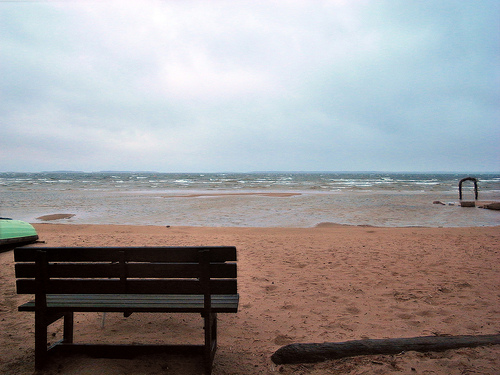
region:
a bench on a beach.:
[16, 239, 248, 356]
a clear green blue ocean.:
[0, 168, 498, 189]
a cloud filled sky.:
[0, 0, 499, 176]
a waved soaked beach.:
[0, 188, 497, 222]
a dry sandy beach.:
[7, 225, 495, 373]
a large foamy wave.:
[324, 173, 446, 190]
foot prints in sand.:
[377, 261, 452, 313]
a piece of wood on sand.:
[267, 315, 498, 364]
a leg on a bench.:
[194, 305, 235, 358]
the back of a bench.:
[9, 241, 257, 304]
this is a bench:
[2, 211, 272, 373]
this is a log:
[268, 293, 493, 373]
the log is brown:
[259, 310, 491, 373]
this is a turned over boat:
[0, 181, 42, 293]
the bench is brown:
[2, 222, 271, 369]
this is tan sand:
[273, 221, 449, 308]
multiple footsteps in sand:
[291, 230, 466, 330]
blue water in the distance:
[0, 141, 470, 193]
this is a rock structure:
[436, 157, 491, 217]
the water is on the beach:
[88, 176, 445, 267]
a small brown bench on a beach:
[11, 243, 243, 373]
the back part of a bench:
[8, 251, 248, 301]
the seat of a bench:
[18, 283, 249, 311]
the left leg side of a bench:
[22, 312, 84, 364]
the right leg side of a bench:
[175, 312, 236, 362]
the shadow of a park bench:
[97, 328, 149, 370]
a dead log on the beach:
[272, 315, 432, 373]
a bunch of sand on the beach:
[297, 252, 374, 307]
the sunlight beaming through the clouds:
[194, 35, 308, 130]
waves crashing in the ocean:
[325, 153, 377, 197]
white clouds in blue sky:
[39, 33, 119, 79]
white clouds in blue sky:
[241, 58, 305, 108]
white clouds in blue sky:
[383, 42, 443, 86]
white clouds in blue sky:
[430, 96, 485, 142]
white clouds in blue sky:
[167, 22, 258, 95]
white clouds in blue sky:
[349, 30, 413, 92]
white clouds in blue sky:
[44, 65, 129, 129]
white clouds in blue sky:
[183, 37, 243, 87]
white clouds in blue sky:
[301, 63, 356, 139]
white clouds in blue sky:
[101, 58, 192, 147]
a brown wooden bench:
[4, 227, 271, 372]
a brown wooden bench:
[14, 237, 281, 372]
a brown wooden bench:
[8, 236, 250, 361]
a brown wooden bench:
[8, 221, 247, 373]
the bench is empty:
[7, 213, 265, 373]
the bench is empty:
[13, 221, 249, 370]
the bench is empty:
[16, 225, 221, 372]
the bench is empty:
[5, 222, 232, 372]